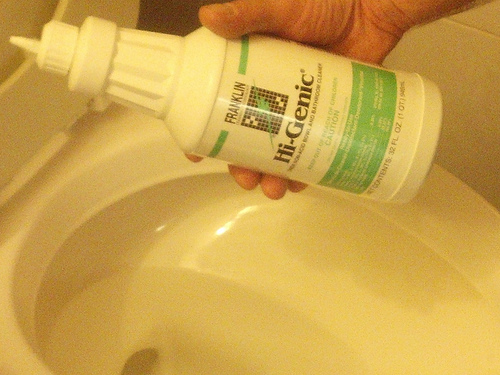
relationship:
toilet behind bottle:
[1, 1, 497, 374] [7, 15, 444, 208]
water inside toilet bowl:
[45, 264, 363, 374] [1, 96, 498, 374]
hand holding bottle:
[197, 1, 488, 196] [7, 15, 444, 208]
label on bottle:
[204, 32, 412, 205] [7, 15, 444, 208]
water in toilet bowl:
[45, 264, 363, 374] [1, 96, 498, 374]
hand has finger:
[197, 1, 488, 196] [229, 164, 261, 191]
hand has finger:
[197, 1, 488, 196] [263, 174, 290, 201]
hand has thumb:
[197, 1, 488, 196] [199, 2, 331, 39]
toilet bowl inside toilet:
[1, 96, 498, 374] [1, 1, 497, 374]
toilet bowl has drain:
[1, 96, 498, 374] [121, 347, 173, 374]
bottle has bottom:
[7, 15, 444, 208] [386, 66, 447, 206]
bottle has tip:
[7, 15, 444, 208] [9, 31, 44, 59]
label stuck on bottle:
[204, 32, 412, 205] [7, 15, 444, 208]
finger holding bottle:
[229, 164, 261, 191] [7, 15, 444, 208]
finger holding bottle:
[263, 174, 290, 201] [7, 15, 444, 208]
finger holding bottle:
[185, 153, 205, 163] [7, 15, 444, 208]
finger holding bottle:
[289, 175, 307, 193] [7, 15, 444, 208]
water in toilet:
[45, 264, 363, 374] [1, 1, 497, 374]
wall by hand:
[139, 1, 499, 216] [197, 1, 488, 196]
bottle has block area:
[7, 15, 444, 208] [321, 57, 400, 195]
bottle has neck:
[7, 15, 444, 208] [73, 16, 197, 126]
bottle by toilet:
[7, 15, 444, 208] [1, 1, 497, 374]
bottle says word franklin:
[7, 15, 444, 208] [220, 79, 249, 129]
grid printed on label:
[239, 85, 288, 133] [204, 32, 412, 205]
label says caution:
[204, 32, 412, 205] [323, 107, 343, 150]